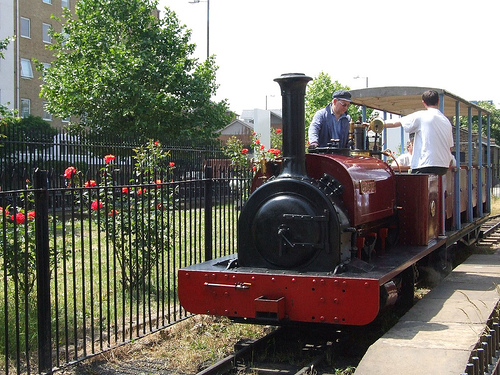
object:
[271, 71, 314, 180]
smoke stack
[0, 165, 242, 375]
fence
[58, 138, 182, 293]
bush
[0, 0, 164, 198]
building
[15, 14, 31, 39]
window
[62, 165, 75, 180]
flowers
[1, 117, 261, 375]
behind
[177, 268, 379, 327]
bumper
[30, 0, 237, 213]
tree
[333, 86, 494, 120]
roof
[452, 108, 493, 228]
sticks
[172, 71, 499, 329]
train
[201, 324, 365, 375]
track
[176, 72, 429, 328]
engine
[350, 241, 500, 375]
platform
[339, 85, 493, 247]
car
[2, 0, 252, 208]
buildings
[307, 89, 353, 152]
engineer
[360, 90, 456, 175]
man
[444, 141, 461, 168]
people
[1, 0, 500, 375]
amusement park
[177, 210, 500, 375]
railroad tracks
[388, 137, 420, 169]
passenger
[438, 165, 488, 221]
seating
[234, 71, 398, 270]
steam engine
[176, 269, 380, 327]
grill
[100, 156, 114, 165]
rose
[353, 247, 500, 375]
ramp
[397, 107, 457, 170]
shirt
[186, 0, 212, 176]
street light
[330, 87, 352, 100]
cap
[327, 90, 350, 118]
head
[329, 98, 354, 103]
sunglasses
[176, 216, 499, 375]
tracks